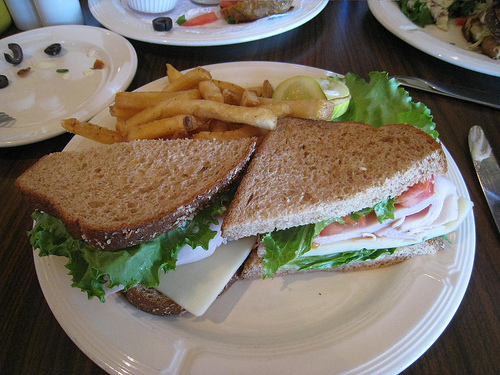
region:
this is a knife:
[411, 72, 481, 106]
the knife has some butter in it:
[466, 119, 498, 211]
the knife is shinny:
[413, 73, 495, 108]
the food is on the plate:
[8, 0, 435, 365]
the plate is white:
[48, 295, 472, 370]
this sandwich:
[26, 142, 465, 289]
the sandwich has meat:
[59, 158, 462, 306]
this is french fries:
[109, 70, 294, 131]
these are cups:
[0, 1, 80, 28]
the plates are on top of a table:
[154, 5, 484, 336]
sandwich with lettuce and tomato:
[216, 105, 471, 313]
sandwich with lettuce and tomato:
[44, 147, 444, 259]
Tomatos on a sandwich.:
[271, 174, 448, 233]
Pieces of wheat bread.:
[173, 113, 423, 252]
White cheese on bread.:
[146, 235, 246, 342]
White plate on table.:
[259, 265, 471, 373]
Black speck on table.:
[288, 276, 331, 313]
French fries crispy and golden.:
[76, 89, 264, 141]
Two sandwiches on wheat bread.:
[25, 112, 490, 330]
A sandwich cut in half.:
[30, 114, 440, 340]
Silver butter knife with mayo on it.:
[456, 105, 499, 232]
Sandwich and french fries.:
[28, 92, 425, 372]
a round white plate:
[28, 60, 476, 374]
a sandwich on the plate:
[13, 110, 471, 317]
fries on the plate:
[61, 60, 337, 142]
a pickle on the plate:
[270, 72, 352, 121]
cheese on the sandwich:
[144, 235, 262, 317]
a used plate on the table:
[0, 25, 138, 148]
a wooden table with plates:
[0, 0, 498, 374]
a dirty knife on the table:
[468, 123, 499, 231]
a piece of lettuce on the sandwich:
[23, 193, 240, 304]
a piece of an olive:
[153, 15, 171, 32]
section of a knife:
[483, 161, 495, 186]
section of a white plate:
[266, 327, 294, 346]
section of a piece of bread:
[290, 164, 312, 181]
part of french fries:
[166, 88, 213, 123]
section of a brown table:
[476, 308, 490, 358]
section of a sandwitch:
[295, 145, 382, 250]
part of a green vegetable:
[368, 87, 395, 109]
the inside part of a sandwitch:
[345, 231, 400, 243]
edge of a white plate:
[444, 45, 465, 71]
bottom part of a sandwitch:
[264, 264, 326, 274]